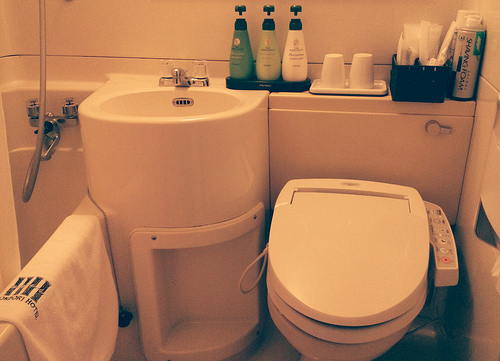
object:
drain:
[168, 95, 195, 108]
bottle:
[225, 2, 253, 83]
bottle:
[253, 1, 283, 82]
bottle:
[278, 1, 310, 82]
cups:
[346, 52, 376, 91]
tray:
[305, 77, 387, 100]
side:
[296, 137, 373, 243]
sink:
[99, 88, 237, 123]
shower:
[156, 51, 205, 111]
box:
[387, 44, 452, 103]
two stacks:
[310, 50, 390, 100]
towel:
[0, 214, 154, 361]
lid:
[263, 178, 435, 321]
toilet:
[264, 87, 473, 360]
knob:
[422, 120, 454, 138]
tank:
[270, 82, 463, 204]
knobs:
[157, 57, 202, 77]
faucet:
[156, 68, 205, 90]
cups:
[317, 52, 345, 89]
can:
[447, 16, 484, 102]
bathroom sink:
[77, 71, 269, 360]